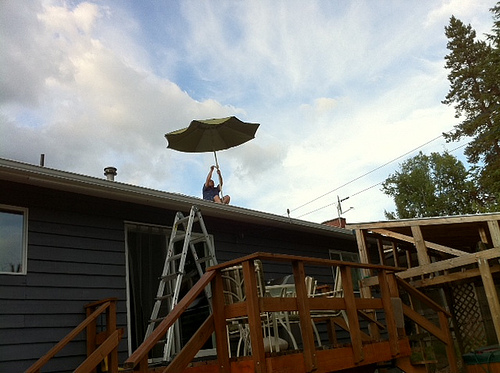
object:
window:
[0, 209, 23, 271]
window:
[331, 252, 340, 279]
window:
[342, 254, 360, 290]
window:
[128, 223, 217, 367]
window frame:
[0, 203, 29, 274]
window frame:
[327, 250, 362, 292]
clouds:
[0, 0, 500, 223]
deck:
[22, 250, 460, 372]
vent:
[104, 166, 117, 181]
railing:
[211, 250, 404, 364]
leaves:
[380, 147, 500, 217]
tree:
[438, 3, 500, 213]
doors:
[118, 215, 226, 367]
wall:
[1, 157, 359, 373]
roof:
[3, 158, 353, 239]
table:
[217, 282, 319, 358]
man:
[202, 162, 231, 205]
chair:
[304, 264, 354, 349]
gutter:
[103, 167, 118, 182]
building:
[0, 157, 500, 373]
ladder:
[144, 205, 235, 364]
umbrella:
[163, 114, 261, 190]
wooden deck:
[21, 252, 461, 373]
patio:
[81, 251, 412, 371]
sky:
[4, 0, 497, 228]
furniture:
[219, 259, 351, 360]